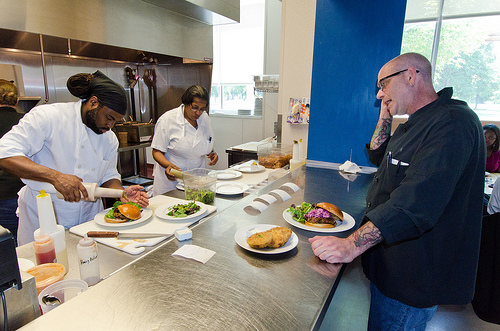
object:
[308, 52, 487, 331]
man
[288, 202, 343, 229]
food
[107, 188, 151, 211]
prepared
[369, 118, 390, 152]
tattoo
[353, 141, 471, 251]
arm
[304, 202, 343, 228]
burger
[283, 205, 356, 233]
plate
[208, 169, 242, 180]
plates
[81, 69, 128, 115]
hat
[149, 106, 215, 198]
uniform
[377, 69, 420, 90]
glasses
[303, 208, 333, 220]
onions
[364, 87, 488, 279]
shirt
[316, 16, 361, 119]
wall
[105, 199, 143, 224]
meal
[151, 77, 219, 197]
woman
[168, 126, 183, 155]
white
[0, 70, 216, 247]
two people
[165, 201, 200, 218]
lettuce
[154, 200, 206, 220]
dish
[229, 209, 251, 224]
countertop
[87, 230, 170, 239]
knife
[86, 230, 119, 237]
handle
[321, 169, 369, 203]
counter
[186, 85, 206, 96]
hair net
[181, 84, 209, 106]
hair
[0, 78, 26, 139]
cook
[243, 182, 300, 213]
four order tickets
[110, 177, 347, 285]
cooking area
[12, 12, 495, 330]
kitchen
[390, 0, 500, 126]
window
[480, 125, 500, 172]
woman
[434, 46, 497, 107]
trees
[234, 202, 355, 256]
two plates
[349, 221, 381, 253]
lower arm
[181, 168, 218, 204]
bowl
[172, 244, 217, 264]
paper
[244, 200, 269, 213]
orders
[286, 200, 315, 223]
salad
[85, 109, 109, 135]
beard